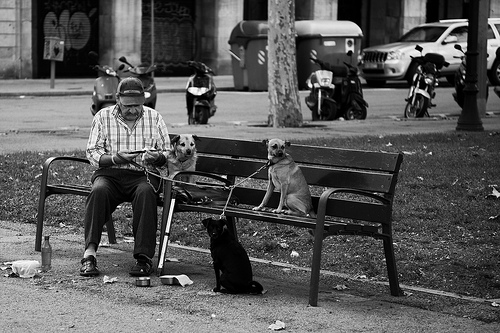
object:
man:
[79, 78, 172, 276]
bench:
[35, 134, 403, 306]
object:
[128, 149, 162, 155]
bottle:
[41, 235, 52, 271]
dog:
[165, 134, 201, 187]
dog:
[202, 217, 264, 293]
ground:
[0, 76, 499, 330]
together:
[164, 134, 316, 293]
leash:
[115, 152, 272, 191]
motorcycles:
[89, 51, 125, 116]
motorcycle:
[185, 60, 218, 125]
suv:
[360, 18, 499, 86]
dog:
[252, 139, 313, 217]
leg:
[382, 235, 402, 296]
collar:
[266, 156, 286, 166]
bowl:
[136, 276, 150, 287]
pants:
[84, 167, 159, 257]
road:
[1, 76, 498, 137]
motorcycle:
[404, 44, 449, 117]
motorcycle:
[305, 53, 338, 121]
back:
[170, 134, 403, 224]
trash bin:
[295, 20, 363, 91]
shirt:
[86, 105, 175, 172]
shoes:
[80, 255, 99, 276]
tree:
[268, 1, 301, 129]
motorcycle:
[340, 50, 369, 120]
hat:
[117, 77, 146, 106]